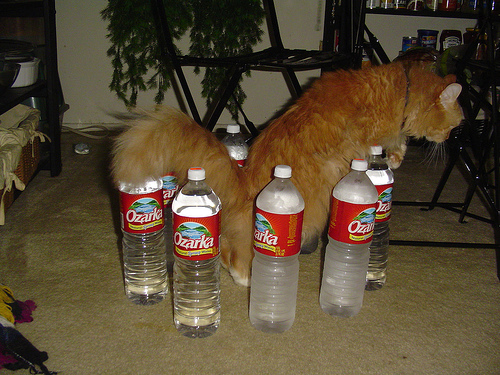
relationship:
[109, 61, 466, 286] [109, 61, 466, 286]
cat has cat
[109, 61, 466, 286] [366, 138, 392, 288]
cat jumping over bottles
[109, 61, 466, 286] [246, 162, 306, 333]
cat jumping over bottles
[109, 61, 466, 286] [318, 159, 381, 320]
cat jumping over bottles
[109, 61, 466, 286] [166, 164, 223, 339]
cat jumping over bottles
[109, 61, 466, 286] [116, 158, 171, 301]
cat jumping over bottles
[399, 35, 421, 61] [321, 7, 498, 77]
food on shelf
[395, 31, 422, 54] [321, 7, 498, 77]
food on shelf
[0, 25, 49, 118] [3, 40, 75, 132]
bowls on shelf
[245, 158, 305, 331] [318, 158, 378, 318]
bottle has water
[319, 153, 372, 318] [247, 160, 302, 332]
bottle has water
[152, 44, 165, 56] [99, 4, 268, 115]
leaf hanging from plant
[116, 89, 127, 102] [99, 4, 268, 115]
leaf hanging from plant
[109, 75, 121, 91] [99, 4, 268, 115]
leaf hanging from plant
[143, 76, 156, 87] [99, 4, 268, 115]
leaf hanging from plant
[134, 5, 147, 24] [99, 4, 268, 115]
leaf hanging from plant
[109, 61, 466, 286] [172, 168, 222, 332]
cat behind bottle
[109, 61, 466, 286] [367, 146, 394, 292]
cat behind bottle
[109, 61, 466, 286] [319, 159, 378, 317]
cat behind bottle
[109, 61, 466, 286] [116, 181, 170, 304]
cat behind bottle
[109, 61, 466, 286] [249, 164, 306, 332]
cat behind bottle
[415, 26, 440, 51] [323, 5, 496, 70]
container on shelf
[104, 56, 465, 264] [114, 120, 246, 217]
cat has tail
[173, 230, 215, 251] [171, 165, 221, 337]
company name on water bottle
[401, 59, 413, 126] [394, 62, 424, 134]
collar on neck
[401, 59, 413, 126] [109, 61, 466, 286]
collar on cat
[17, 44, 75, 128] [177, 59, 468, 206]
cookware near cat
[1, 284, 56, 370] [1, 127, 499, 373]
clothing laying on carpet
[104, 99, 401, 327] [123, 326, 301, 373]
bottles on floor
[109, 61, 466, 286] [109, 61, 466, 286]
cat on cat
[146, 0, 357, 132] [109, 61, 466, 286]
chair behind cat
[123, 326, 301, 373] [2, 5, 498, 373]
floor of room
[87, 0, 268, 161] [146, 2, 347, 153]
plant near chair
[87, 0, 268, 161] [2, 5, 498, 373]
plant in room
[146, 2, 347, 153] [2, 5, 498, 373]
chair in room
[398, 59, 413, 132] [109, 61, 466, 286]
collar on cat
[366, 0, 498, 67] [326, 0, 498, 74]
can goods on shelves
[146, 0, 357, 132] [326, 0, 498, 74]
chair near shelves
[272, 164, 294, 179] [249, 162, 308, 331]
top on water bottle